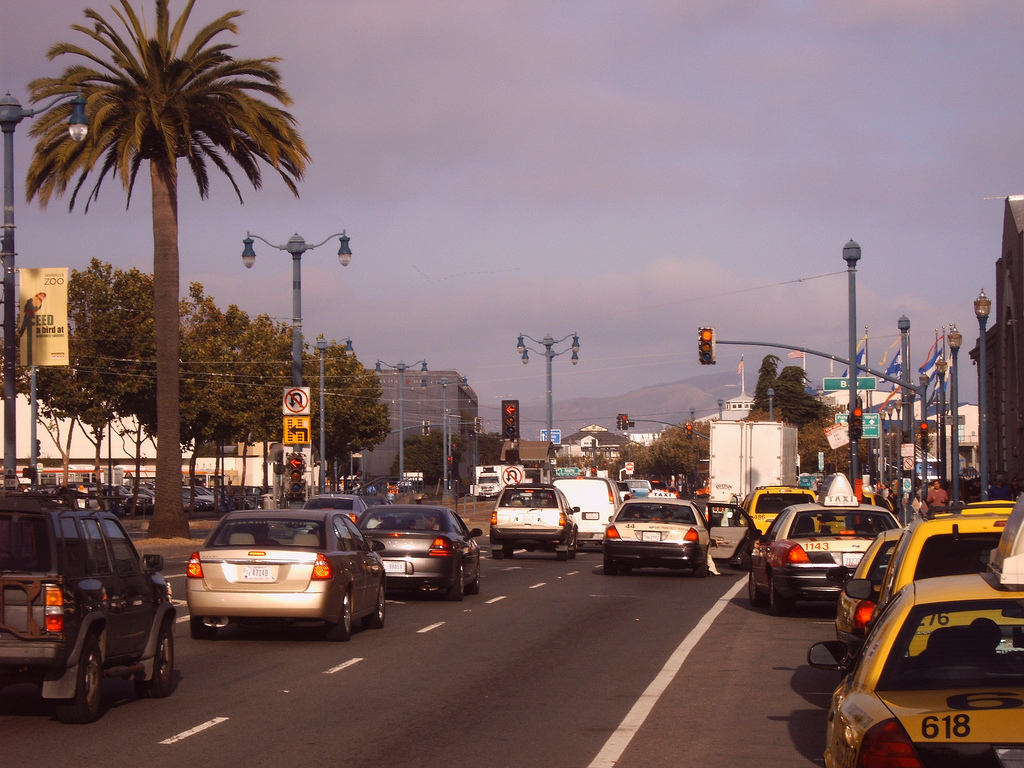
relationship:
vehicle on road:
[597, 493, 703, 556] [1, 482, 848, 766]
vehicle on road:
[485, 478, 563, 531] [1, 482, 848, 766]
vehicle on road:
[373, 510, 480, 590] [1, 482, 848, 766]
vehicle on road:
[180, 504, 375, 634] [1, 482, 848, 766]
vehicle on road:
[1, 493, 183, 707] [1, 482, 848, 766]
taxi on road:
[828, 549, 1023, 766] [1, 482, 848, 766]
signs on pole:
[278, 376, 318, 476] [286, 230, 308, 522]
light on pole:
[688, 322, 714, 366] [721, 333, 903, 388]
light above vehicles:
[498, 392, 529, 447] [487, 448, 725, 559]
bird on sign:
[14, 275, 58, 368] [1, 269, 79, 391]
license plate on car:
[209, 550, 298, 594] [180, 493, 397, 634]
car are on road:
[57, 536, 133, 655] [1, 528, 885, 762]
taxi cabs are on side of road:
[719, 476, 1020, 764] [1, 528, 885, 762]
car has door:
[608, 469, 742, 577] [692, 513, 755, 565]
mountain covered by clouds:
[435, 359, 792, 466] [6, 14, 1020, 462]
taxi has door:
[591, 500, 760, 593] [699, 500, 769, 574]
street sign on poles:
[798, 355, 894, 446] [816, 238, 869, 493]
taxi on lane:
[584, 476, 760, 587] [181, 532, 765, 764]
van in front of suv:
[550, 467, 620, 556] [477, 465, 586, 565]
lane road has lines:
[1, 545, 717, 759] [152, 565, 751, 760]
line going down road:
[599, 605, 701, 729] [385, 573, 563, 707]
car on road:
[57, 536, 133, 655] [294, 677, 474, 736]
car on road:
[350, 485, 526, 628] [459, 586, 607, 716]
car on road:
[472, 437, 598, 576] [465, 586, 746, 720]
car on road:
[608, 469, 742, 576] [441, 547, 740, 707]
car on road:
[413, 441, 571, 552] [552, 601, 738, 720]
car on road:
[173, 467, 256, 534] [456, 657, 591, 720]